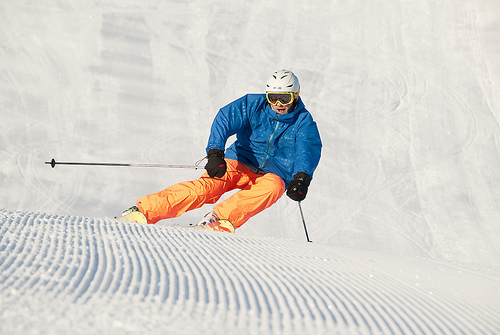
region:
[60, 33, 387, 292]
a person skiing on the snow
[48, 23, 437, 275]
a peron skiing on a hill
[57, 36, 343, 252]
a person kiing on snow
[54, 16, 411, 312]
a skier on the snow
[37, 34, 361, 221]
a person holding skiing poles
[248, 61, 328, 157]
a person wearing a helmet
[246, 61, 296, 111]
a person wearing a white helmet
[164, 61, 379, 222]
a person wearing a jacket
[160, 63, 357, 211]
a person wearing a blue jacket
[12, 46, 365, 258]
a skier in the snow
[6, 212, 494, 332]
ridges in the snow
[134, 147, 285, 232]
the skier is wearing orange snowpants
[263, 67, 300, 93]
a white helmet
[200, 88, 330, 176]
a blue snow coat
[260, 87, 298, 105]
the skier is wearing yellow goggles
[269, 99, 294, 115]
the skier's mouth is open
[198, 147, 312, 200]
the skier is wearing black gloves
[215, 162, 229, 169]
a red spot on the glove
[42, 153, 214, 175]
a ski pole stretched out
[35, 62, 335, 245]
person skiing in the snow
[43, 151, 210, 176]
a pole used in skiing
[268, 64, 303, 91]
white helmet on person's head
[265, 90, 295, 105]
sunglasses on person skiing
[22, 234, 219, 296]
tracks in snow from skiing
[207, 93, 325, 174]
blue jacket for cold weather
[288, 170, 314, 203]
left glove on person's hand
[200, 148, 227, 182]
right glove on person's hand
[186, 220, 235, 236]
part of ski on person's foot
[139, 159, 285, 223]
orange pants for cold weather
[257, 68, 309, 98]
helmet is white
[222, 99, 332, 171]
jacket is blue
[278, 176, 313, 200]
gloves are black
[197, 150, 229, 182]
gloves are black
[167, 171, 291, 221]
the pnats are orange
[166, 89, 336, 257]
the guy is slanting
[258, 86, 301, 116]
goggles cover the face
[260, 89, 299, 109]
goggles are yellow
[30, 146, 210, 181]
skipole is in the air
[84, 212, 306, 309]
skitrail is on the snow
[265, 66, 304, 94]
white helmet on skier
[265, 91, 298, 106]
yellow goggles on lone skier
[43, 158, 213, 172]
ski pole in skier's right hand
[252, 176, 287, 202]
skier's left knee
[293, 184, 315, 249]
ski pole in skier's left hand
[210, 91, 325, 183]
blue jacket on lone skier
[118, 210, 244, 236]
bottom of orange skis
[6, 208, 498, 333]
snow with tracks in it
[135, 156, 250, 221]
right leg in orange pants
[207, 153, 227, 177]
skier's right hand